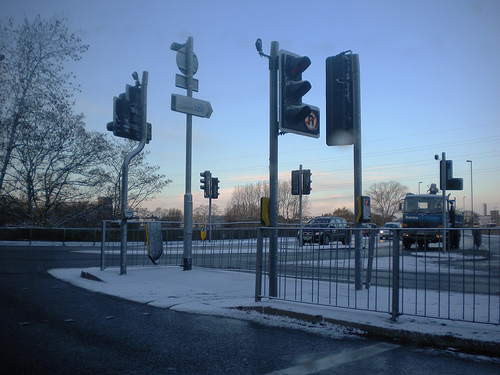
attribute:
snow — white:
[46, 262, 499, 360]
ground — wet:
[2, 243, 500, 375]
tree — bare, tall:
[0, 12, 90, 191]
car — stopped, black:
[299, 216, 351, 248]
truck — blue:
[401, 193, 463, 250]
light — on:
[402, 232, 410, 239]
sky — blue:
[1, 3, 499, 218]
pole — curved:
[118, 73, 147, 277]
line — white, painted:
[267, 332, 402, 374]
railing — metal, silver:
[255, 226, 500, 332]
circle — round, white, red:
[305, 111, 317, 131]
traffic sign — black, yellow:
[259, 199, 272, 228]